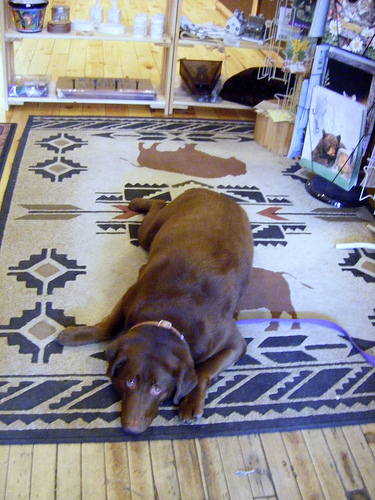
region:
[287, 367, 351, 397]
black lone on carpet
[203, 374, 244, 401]
black lone on carpet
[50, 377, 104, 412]
black lone on carpet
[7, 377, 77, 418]
black lone on carpet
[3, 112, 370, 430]
A large area rug.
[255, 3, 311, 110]
A wire rack holding things for sale.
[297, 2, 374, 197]
A black stand holding things for sale.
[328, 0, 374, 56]
A picture with daisies.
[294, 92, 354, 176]
Picture of a bear.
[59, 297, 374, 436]
Blue leash for dog.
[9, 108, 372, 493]
Wood floor under area rug.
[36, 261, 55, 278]
brown diamond on carpet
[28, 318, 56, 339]
brown diamond on carpet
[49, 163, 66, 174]
brown diamond on carpet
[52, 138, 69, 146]
brown diamond on carpet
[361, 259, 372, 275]
brown diamond on carpet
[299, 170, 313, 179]
brown diamond on carpet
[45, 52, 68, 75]
brown diamond on carpet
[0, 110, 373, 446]
a carpet with a Native American print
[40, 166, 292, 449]
a dog with chocolate colored fur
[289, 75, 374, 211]
a book with a brown bear on the cover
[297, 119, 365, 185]
a bear on the cover of a book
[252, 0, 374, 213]
a rack of books and cards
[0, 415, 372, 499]
a wooden floor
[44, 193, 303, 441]
the dog has a collar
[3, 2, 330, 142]
shelves with souvenirs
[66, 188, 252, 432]
a brown down is laying down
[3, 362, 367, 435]
blue pattern on the rug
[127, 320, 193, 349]
a light brown collar on the dog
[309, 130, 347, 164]
a bear on the book cover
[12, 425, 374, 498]
real wood floors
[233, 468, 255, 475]
trash on the ground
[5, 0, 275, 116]
a wooden shelf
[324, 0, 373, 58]
white flower on the cover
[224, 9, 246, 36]
small house figurine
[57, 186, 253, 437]
Brown dog laying on a rug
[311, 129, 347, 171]
Picture of a large brown bear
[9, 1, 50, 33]
Blue pot with colorful designs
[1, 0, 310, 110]
White shelves containing miscellaneous items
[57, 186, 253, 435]
Dog lounging on brown rug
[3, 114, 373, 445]
Brown dog laying on buffalo rug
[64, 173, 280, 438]
Brown dog laying on the carpet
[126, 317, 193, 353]
dog wearing a collar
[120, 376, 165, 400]
dog has brown eyes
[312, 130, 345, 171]
bear on the picture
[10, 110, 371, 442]
blue and white carpet on the floor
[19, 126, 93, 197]
blue shield on the carpet